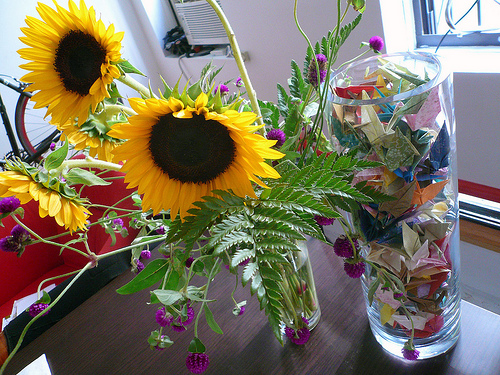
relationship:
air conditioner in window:
[172, 1, 213, 57] [406, 2, 493, 56]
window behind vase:
[406, 2, 493, 56] [310, 57, 471, 361]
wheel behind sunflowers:
[17, 74, 69, 154] [14, 16, 275, 239]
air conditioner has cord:
[172, 1, 213, 57] [172, 39, 210, 64]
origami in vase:
[363, 69, 449, 328] [310, 57, 471, 361]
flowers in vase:
[15, 19, 337, 330] [220, 246, 340, 342]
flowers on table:
[15, 19, 337, 330] [14, 229, 354, 371]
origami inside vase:
[363, 69, 449, 328] [310, 57, 471, 361]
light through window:
[444, 0, 497, 25] [406, 2, 493, 56]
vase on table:
[220, 246, 340, 342] [14, 229, 354, 371]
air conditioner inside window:
[172, 1, 213, 57] [406, 2, 493, 56]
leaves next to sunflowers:
[178, 159, 355, 331] [14, 16, 275, 239]